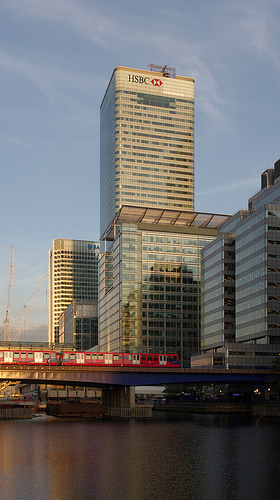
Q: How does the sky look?
A: Partly cloudy.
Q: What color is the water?
A: Brown.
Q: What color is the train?
A: Red.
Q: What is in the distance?
A: A crane.